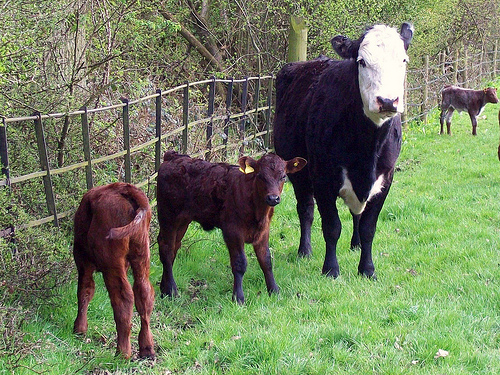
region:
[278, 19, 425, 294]
black and white cow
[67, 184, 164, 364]
red baby cow eating grass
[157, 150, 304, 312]
baby cow standing in grass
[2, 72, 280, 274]
unfinished wood barrier fence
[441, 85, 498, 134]
baby cow next to fence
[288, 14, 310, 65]
unfinished wood fence post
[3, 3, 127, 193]
trees next to wood fence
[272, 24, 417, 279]
cow standing next to calf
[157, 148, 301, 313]
brown calf standing next to cow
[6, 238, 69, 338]
patch of dead grass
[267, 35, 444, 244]
the cow is white and black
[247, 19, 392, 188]
the cow is white and black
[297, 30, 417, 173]
the cow is white and black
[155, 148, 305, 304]
dark brown calf next to cow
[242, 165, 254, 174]
yellow tag in calf ear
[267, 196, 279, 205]
black nose on brown calf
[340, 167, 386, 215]
white fur on underside of black cow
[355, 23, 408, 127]
cow has a white face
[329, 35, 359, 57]
back ear on cow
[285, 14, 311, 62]
green wood post behind large cow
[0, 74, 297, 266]
fence behind calf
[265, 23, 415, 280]
cow in front of fence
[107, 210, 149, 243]
calf tail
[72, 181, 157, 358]
the rear end of a calf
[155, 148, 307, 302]
a young brown calf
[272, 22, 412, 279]
a big adult cow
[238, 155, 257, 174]
a calf's right ear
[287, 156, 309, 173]
a calf's left ear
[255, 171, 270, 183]
a calf's right eye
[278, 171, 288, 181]
a calf's left eye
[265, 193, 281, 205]
a calf's nose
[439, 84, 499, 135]
a calf in the distance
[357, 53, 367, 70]
a cow's right eye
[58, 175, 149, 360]
a brown calf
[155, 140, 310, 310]
a dark brown calf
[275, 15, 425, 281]
a black and white cow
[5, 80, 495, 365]
a green grassy field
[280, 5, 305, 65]
a wood fence post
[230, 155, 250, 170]
a yellow tag in a calf's ear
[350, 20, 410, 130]
the white face of a cow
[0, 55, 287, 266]
a fence behind some cows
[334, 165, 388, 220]
the white chest on a cow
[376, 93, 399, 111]
a black nose on a cow